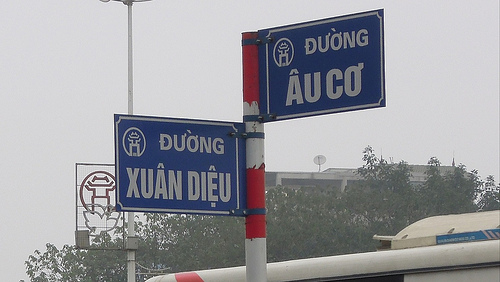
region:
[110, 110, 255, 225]
street sign with writing on it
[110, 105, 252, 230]
possibly vietnamese writing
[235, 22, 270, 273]
striped pole with signs on it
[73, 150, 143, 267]
not illuminated neon sign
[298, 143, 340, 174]
sattelite dish on top of building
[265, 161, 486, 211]
concrete building in background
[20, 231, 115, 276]
foilage and other trees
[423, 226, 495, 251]
blue sign with writing on it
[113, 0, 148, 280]
very tall light pole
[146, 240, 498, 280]
possibly a bus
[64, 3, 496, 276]
two blue signs on pole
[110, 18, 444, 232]
two blue signs on metal pole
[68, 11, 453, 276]
two street signs on pole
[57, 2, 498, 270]
two street signs on metal pole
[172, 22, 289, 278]
a red and white pole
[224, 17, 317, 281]
red and white metal pole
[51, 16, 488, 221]
street signs on pole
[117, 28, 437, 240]
street signs on metal pole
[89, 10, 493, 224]
blue signs on pole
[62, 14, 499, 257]
blue signs on metal pole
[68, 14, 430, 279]
two street signs on a pole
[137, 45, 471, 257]
two blue signs on a pole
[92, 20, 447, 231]
two blue street signs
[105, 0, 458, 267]
two blue street signs on a metal pole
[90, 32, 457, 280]
two street signs on a metal pole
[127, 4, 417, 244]
two signs on a metal pole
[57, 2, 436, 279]
blue signs on a pole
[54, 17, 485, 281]
signs on a metal pole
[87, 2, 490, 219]
street signs on a pole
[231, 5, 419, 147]
sign hanging on a red and white pole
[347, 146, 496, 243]
dark green trees next to building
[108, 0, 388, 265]
two signs on a colorful pole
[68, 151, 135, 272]
strange sign hanging from white pole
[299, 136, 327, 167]
satellite dish on top of building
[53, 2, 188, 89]
one white pole in fog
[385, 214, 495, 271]
building with blue and white striped sign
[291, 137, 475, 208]
foggy skies with green trees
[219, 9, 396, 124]
sign in a foreign language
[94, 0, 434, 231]
two blue signs in foreign language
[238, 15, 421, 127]
a display of board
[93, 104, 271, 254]
a big display board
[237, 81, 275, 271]
a long poll on road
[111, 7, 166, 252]
a very long poll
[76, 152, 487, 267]
a group of trees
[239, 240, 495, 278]
a small white pipe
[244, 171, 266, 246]
a red mark on pipe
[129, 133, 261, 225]
white text written in board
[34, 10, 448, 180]
a beautiful view of sky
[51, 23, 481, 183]
sky with no clouds